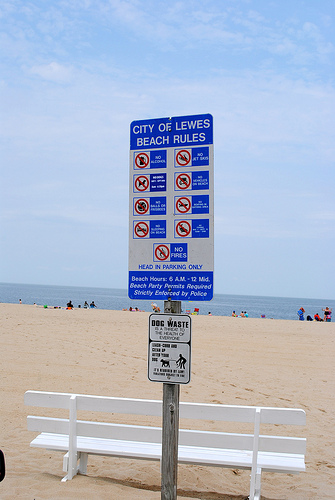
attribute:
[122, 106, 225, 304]
sign — white, blue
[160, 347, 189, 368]
icon — dog, human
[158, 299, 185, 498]
pole — wooden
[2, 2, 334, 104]
blue sky — clear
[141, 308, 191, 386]
sign — white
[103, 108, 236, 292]
post — wood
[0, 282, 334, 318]
ocean water — beautiful, blue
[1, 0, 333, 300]
sky — blue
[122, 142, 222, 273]
circles — red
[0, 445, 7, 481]
trashcan — trash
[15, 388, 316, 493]
bench — wooden, white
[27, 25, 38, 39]
clouds — white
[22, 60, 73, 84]
clouds — white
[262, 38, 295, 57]
clouds — white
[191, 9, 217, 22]
clouds — white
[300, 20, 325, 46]
clouds — white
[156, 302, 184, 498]
pole — wood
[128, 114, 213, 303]
sign — blue and white, blue, beach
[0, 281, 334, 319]
water — calm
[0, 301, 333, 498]
sand — clean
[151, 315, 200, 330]
sign — black, white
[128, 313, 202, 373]
sign — white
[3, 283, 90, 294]
beach — calm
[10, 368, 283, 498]
bench — white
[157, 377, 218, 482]
bar — wooden